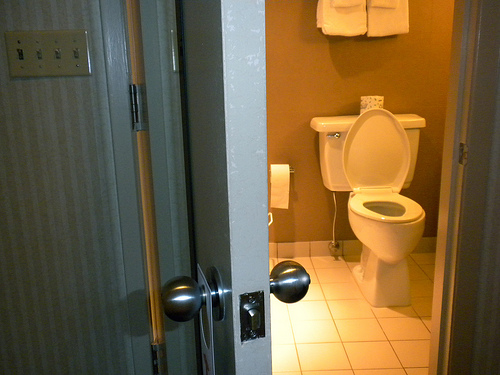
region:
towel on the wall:
[325, 2, 413, 34]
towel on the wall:
[334, 4, 364, 49]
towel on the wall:
[375, 0, 417, 41]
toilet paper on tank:
[352, 92, 387, 111]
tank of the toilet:
[315, 112, 352, 131]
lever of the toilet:
[308, 128, 346, 144]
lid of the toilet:
[347, 105, 400, 186]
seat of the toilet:
[362, 193, 412, 217]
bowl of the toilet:
[370, 193, 405, 216]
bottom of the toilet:
[385, 290, 411, 307]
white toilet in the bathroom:
[307, 111, 425, 306]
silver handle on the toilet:
[323, 129, 343, 140]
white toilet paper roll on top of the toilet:
[356, 92, 385, 116]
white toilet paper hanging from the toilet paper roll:
[267, 161, 292, 211]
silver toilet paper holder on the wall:
[265, 166, 295, 172]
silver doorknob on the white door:
[267, 258, 312, 305]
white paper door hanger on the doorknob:
[190, 263, 218, 373]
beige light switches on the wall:
[0, 25, 97, 82]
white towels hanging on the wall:
[312, 0, 412, 40]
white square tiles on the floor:
[268, 234, 438, 374]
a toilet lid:
[352, 125, 399, 185]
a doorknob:
[163, 278, 198, 323]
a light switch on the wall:
[5, 32, 98, 74]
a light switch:
[7, 34, 84, 71]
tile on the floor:
[298, 326, 364, 366]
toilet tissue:
[271, 164, 295, 209]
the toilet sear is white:
[374, 211, 384, 219]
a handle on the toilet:
[321, 132, 341, 144]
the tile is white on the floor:
[333, 314, 393, 344]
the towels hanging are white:
[320, 1, 409, 32]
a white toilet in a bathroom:
[310, 113, 426, 305]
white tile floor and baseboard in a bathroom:
[268, 237, 436, 373]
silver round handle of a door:
[271, 258, 311, 303]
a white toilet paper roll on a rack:
[269, 162, 289, 209]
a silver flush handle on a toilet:
[324, 131, 341, 138]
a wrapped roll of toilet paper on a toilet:
[358, 93, 385, 113]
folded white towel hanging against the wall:
[316, 2, 411, 36]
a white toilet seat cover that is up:
[342, 108, 409, 193]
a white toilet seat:
[351, 192, 422, 222]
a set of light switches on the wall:
[4, 32, 91, 79]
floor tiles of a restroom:
[311, 250, 349, 277]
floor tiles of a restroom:
[337, 290, 367, 315]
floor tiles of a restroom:
[281, 325, 320, 354]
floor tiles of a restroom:
[288, 345, 318, 370]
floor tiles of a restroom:
[352, 336, 392, 363]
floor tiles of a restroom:
[380, 302, 410, 344]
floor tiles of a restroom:
[391, 342, 423, 374]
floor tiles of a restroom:
[410, 250, 429, 283]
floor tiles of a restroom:
[416, 276, 442, 299]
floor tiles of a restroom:
[412, 299, 434, 325]